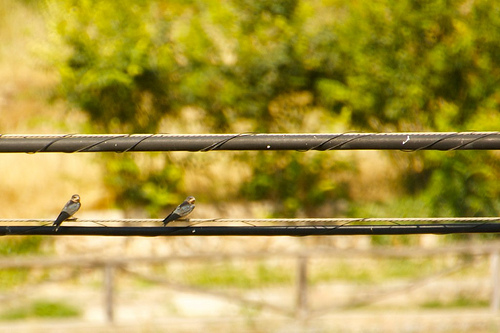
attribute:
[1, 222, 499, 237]
cable — black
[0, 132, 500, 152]
cable — thin, black, larger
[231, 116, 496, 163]
cables — different colors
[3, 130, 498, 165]
cable — large, black